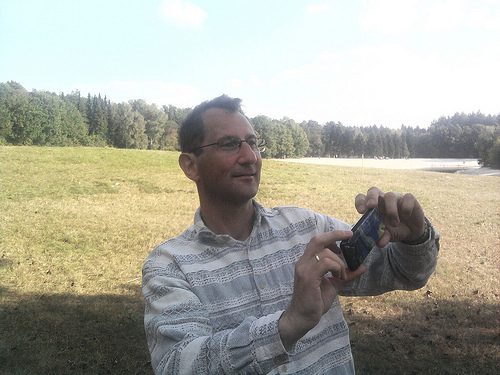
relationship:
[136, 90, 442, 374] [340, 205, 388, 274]
man holding phone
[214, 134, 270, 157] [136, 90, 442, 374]
glasses of man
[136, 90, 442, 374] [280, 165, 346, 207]
man standing in field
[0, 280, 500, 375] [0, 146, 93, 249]
shadow on field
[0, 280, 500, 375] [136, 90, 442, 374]
shadow behind man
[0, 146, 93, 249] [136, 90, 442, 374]
field behind man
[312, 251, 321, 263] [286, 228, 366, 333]
ring on hand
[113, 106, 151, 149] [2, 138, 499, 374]
tree around field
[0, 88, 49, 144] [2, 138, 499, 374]
tree around field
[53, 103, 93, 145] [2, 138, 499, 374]
tree around field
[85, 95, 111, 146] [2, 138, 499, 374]
tree around field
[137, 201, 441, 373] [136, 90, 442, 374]
shirt of man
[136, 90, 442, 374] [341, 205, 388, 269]
man holding camera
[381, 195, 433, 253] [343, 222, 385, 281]
man's hand holding camera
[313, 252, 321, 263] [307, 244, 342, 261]
ring on finger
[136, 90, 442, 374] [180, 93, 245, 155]
man has hair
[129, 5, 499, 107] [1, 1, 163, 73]
clouds in sky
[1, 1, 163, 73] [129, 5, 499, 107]
sky has clouds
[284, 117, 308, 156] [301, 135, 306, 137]
tree has leaf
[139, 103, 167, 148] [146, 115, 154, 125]
tree has leaf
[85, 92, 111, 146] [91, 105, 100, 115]
tree has leaf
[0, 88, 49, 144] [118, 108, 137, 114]
tree has leaf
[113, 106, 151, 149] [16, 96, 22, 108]
tree has leaf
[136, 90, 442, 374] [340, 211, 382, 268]
man has phone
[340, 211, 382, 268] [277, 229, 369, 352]
phone in hand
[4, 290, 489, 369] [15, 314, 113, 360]
shadow on grass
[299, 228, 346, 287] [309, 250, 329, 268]
finger with ring